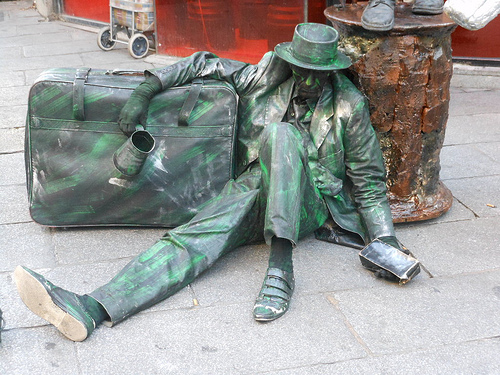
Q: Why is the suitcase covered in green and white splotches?
A: Someone painted.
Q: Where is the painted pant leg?
A: On the man.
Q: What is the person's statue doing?
A: Sitting down.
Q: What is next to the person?
A: A suitcase.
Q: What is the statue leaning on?
A: A pedestal.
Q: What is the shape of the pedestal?
A: Cylinder.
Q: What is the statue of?
A: A man.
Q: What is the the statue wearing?
A: Shoes.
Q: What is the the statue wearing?
A: A suit.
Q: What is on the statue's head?
A: A hat.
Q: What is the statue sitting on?
A: The ground.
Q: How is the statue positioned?
A: Sitting on the ground.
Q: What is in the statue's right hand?
A: A cup.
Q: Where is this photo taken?
A: On a sidewalk.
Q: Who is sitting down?
A: A man.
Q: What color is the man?
A: Green.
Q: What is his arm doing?
A: Resting on a suitcase.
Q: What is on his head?
A: A hat.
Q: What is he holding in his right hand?
A: A cup.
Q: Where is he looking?
A: Down.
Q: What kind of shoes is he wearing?
A: Dress shoes.